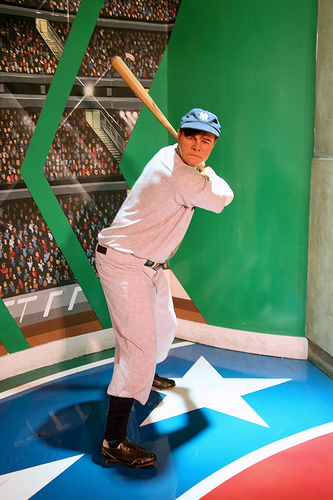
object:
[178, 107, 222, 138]
baseball cap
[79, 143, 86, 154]
fan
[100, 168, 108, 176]
fan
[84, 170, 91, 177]
fan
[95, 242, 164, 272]
belt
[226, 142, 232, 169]
ground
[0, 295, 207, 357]
wood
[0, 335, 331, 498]
floor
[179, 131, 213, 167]
face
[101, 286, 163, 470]
leg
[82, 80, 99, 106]
white baseball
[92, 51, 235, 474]
statue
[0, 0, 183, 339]
backdrop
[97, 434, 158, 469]
shoe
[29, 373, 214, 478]
shadow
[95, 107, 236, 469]
babe ruth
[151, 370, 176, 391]
shoe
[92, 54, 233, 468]
wax figure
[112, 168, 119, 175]
fans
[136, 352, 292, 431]
star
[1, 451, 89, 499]
star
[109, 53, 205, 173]
baseball bat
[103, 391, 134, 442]
black socks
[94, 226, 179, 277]
waist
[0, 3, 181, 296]
illustration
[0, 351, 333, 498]
background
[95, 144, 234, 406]
uniform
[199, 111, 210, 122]
logo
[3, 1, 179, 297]
picture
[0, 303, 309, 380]
base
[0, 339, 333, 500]
ground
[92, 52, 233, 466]
figure